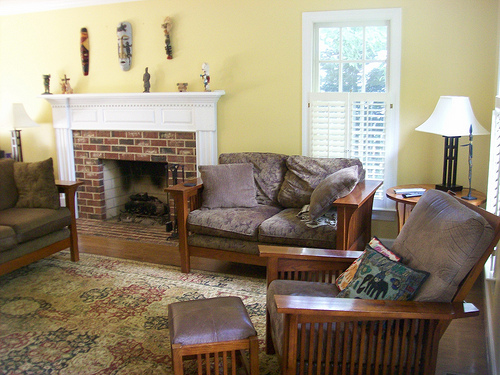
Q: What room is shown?
A: It is a living room.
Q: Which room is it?
A: It is a living room.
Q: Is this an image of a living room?
A: Yes, it is showing a living room.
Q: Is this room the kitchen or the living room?
A: It is the living room.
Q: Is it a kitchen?
A: No, it is a living room.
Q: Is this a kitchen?
A: No, it is a living room.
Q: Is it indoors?
A: Yes, it is indoors.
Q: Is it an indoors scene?
A: Yes, it is indoors.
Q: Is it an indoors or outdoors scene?
A: It is indoors.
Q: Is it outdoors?
A: No, it is indoors.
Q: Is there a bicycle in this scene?
A: No, there are no bicycles.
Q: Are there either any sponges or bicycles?
A: No, there are no bicycles or sponges.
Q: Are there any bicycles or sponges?
A: No, there are no bicycles or sponges.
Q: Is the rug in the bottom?
A: Yes, the rug is in the bottom of the image.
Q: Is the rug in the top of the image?
A: No, the rug is in the bottom of the image.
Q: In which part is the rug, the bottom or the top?
A: The rug is in the bottom of the image.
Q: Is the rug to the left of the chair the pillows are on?
A: Yes, the rug is to the left of the chair.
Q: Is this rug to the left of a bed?
A: No, the rug is to the left of the chair.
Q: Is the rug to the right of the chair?
A: No, the rug is to the left of the chair.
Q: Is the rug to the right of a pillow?
A: No, the rug is to the left of a pillow.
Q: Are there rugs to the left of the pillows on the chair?
A: Yes, there is a rug to the left of the pillows.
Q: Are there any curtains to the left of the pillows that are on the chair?
A: No, there is a rug to the left of the pillows.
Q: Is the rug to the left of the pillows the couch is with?
A: Yes, the rug is to the left of the pillows.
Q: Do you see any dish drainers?
A: No, there are no dish drainers.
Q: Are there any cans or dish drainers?
A: No, there are no dish drainers or cans.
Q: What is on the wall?
A: The decorations are on the wall.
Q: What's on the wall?
A: The decorations are on the wall.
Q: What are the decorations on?
A: The decorations are on the wall.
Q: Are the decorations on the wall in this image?
A: Yes, the decorations are on the wall.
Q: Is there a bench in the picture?
A: No, there are no benches.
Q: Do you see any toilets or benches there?
A: No, there are no benches or toilets.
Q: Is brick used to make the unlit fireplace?
A: Yes, the fireplace is made of brick.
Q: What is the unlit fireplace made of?
A: The fire place is made of brick.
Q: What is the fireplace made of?
A: The fire place is made of brick.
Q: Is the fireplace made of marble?
A: No, the fireplace is made of brick.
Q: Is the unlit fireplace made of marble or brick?
A: The fireplace is made of brick.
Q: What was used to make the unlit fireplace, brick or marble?
A: The fireplace is made of brick.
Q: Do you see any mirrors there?
A: No, there are no mirrors.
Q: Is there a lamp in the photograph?
A: Yes, there is a lamp.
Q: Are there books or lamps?
A: Yes, there is a lamp.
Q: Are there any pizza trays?
A: No, there are no pizza trays.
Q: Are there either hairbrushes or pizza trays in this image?
A: No, there are no pizza trays or hairbrushes.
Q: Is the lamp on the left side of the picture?
A: No, the lamp is on the right of the image.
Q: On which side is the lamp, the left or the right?
A: The lamp is on the right of the image.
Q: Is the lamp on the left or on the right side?
A: The lamp is on the right of the image.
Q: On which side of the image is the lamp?
A: The lamp is on the right of the image.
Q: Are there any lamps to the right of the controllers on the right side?
A: Yes, there is a lamp to the right of the controllers.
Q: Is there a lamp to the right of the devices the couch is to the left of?
A: Yes, there is a lamp to the right of the controllers.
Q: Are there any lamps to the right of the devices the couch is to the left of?
A: Yes, there is a lamp to the right of the controllers.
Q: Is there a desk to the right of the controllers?
A: No, there is a lamp to the right of the controllers.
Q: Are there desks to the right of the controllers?
A: No, there is a lamp to the right of the controllers.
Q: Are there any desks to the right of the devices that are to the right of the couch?
A: No, there is a lamp to the right of the controllers.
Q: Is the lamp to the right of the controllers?
A: Yes, the lamp is to the right of the controllers.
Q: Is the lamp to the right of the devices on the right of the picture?
A: Yes, the lamp is to the right of the controllers.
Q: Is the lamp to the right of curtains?
A: No, the lamp is to the right of the controllers.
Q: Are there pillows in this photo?
A: Yes, there is a pillow.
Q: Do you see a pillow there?
A: Yes, there is a pillow.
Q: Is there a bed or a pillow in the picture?
A: Yes, there is a pillow.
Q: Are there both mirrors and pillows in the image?
A: No, there is a pillow but no mirrors.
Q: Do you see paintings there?
A: No, there are no paintings.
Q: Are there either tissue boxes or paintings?
A: No, there are no paintings or tissue boxes.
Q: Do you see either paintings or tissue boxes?
A: No, there are no paintings or tissue boxes.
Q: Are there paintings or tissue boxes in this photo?
A: No, there are no paintings or tissue boxes.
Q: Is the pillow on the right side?
A: Yes, the pillow is on the right of the image.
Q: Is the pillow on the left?
A: No, the pillow is on the right of the image.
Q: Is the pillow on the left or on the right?
A: The pillow is on the right of the image.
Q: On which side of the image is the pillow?
A: The pillow is on the right of the image.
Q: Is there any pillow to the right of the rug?
A: Yes, there is a pillow to the right of the rug.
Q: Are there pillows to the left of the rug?
A: No, the pillow is to the right of the rug.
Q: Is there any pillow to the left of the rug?
A: No, the pillow is to the right of the rug.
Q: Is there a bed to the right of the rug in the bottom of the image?
A: No, there is a pillow to the right of the rug.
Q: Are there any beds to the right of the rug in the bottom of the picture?
A: No, there is a pillow to the right of the rug.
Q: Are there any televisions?
A: No, there are no televisions.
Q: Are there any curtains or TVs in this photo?
A: No, there are no TVs or curtains.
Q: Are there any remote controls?
A: Yes, there is a remote control.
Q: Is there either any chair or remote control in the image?
A: Yes, there is a remote control.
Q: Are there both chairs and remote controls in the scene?
A: Yes, there are both a remote control and a chair.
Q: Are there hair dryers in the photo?
A: No, there are no hair dryers.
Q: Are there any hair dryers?
A: No, there are no hair dryers.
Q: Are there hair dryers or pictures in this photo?
A: No, there are no hair dryers or pictures.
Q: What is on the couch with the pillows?
A: The remote control is on the couch.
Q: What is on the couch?
A: The remote control is on the couch.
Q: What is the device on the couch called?
A: The device is a remote control.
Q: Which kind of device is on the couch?
A: The device is a remote control.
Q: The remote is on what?
A: The remote is on the couch.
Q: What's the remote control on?
A: The remote is on the couch.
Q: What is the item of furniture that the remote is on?
A: The piece of furniture is a couch.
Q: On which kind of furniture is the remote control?
A: The remote is on the couch.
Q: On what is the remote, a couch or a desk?
A: The remote is on a couch.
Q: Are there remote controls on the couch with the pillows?
A: Yes, there is a remote control on the couch.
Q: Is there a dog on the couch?
A: No, there is a remote control on the couch.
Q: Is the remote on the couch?
A: Yes, the remote is on the couch.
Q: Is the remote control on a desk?
A: No, the remote control is on the couch.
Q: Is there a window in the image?
A: Yes, there is a window.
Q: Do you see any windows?
A: Yes, there is a window.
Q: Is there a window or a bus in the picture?
A: Yes, there is a window.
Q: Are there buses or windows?
A: Yes, there is a window.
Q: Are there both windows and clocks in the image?
A: No, there is a window but no clocks.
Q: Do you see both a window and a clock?
A: No, there is a window but no clocks.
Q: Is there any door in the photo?
A: No, there are no doors.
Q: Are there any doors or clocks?
A: No, there are no doors or clocks.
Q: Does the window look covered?
A: Yes, the window is covered.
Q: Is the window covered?
A: Yes, the window is covered.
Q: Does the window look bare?
A: No, the window is covered.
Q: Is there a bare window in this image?
A: No, there is a window but it is covered.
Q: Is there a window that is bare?
A: No, there is a window but it is covered.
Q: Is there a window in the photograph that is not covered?
A: No, there is a window but it is covered.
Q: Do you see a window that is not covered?
A: No, there is a window but it is covered.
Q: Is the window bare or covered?
A: The window is covered.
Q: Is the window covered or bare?
A: The window is covered.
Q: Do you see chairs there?
A: Yes, there is a chair.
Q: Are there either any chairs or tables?
A: Yes, there is a chair.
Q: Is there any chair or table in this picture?
A: Yes, there is a chair.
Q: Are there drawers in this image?
A: No, there are no drawers.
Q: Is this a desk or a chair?
A: This is a chair.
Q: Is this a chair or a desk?
A: This is a chair.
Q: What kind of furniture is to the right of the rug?
A: The piece of furniture is a chair.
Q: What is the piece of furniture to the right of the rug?
A: The piece of furniture is a chair.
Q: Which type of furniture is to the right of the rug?
A: The piece of furniture is a chair.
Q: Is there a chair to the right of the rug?
A: Yes, there is a chair to the right of the rug.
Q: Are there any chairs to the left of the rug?
A: No, the chair is to the right of the rug.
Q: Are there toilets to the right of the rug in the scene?
A: No, there is a chair to the right of the rug.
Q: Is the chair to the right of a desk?
A: No, the chair is to the right of a rug.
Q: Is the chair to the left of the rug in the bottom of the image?
A: No, the chair is to the right of the rug.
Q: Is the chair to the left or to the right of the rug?
A: The chair is to the right of the rug.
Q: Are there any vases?
A: No, there are no vases.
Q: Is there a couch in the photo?
A: Yes, there is a couch.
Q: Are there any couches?
A: Yes, there is a couch.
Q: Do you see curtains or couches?
A: Yes, there is a couch.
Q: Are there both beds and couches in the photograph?
A: No, there is a couch but no beds.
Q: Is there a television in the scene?
A: No, there are no televisions.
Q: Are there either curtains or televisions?
A: No, there are no televisions or curtains.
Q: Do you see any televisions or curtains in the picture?
A: No, there are no televisions or curtains.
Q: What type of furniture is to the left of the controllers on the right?
A: The piece of furniture is a couch.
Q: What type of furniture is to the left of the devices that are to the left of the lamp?
A: The piece of furniture is a couch.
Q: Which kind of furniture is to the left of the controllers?
A: The piece of furniture is a couch.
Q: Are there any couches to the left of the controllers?
A: Yes, there is a couch to the left of the controllers.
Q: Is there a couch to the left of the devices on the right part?
A: Yes, there is a couch to the left of the controllers.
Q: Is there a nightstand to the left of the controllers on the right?
A: No, there is a couch to the left of the controllers.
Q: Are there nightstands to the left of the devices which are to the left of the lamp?
A: No, there is a couch to the left of the controllers.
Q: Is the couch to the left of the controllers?
A: Yes, the couch is to the left of the controllers.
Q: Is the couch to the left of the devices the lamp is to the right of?
A: Yes, the couch is to the left of the controllers.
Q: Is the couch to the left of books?
A: No, the couch is to the left of the controllers.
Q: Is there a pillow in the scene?
A: Yes, there are pillows.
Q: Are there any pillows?
A: Yes, there are pillows.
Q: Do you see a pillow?
A: Yes, there are pillows.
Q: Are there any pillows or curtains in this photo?
A: Yes, there are pillows.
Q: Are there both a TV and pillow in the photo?
A: No, there are pillows but no televisions.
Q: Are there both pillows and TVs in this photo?
A: No, there are pillows but no televisions.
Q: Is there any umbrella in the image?
A: No, there are no umbrellas.